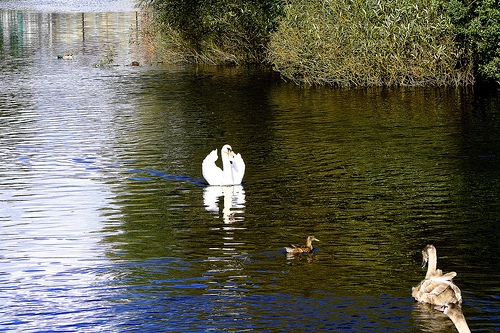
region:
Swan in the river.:
[199, 139, 246, 189]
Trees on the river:
[132, 1, 498, 99]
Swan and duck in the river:
[190, 130, 331, 270]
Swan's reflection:
[200, 181, 250, 229]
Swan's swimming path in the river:
[72, 146, 205, 189]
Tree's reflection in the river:
[275, 80, 462, 286]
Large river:
[0, 6, 488, 328]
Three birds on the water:
[200, 141, 465, 311]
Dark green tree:
[138, 0, 273, 67]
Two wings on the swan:
[200, 145, 247, 187]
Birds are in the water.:
[203, 145, 469, 330]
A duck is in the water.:
[279, 228, 319, 259]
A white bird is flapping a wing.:
[198, 144, 248, 187]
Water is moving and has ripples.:
[3, 0, 493, 327]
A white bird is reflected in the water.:
[200, 145, 247, 230]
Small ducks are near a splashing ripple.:
[58, 50, 140, 67]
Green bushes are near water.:
[136, 0, 496, 91]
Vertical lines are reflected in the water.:
[2, 0, 140, 45]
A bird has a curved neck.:
[414, 242, 476, 331]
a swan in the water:
[200, 138, 252, 191]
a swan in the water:
[409, 242, 474, 330]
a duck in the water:
[278, 233, 328, 262]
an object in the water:
[48, 50, 78, 64]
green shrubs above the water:
[127, 0, 496, 89]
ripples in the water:
[18, 132, 198, 201]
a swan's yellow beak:
[227, 148, 234, 156]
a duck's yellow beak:
[313, 235, 319, 245]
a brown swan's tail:
[440, 293, 479, 332]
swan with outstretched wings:
[189, 126, 295, 210]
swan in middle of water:
[191, 124, 268, 204]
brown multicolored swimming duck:
[283, 225, 365, 290]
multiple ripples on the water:
[348, 139, 398, 224]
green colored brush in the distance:
[283, 18, 368, 75]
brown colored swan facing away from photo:
[401, 233, 479, 330]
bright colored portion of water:
[28, 107, 61, 202]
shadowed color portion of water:
[332, 118, 421, 209]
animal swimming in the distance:
[37, 42, 86, 68]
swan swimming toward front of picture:
[183, 130, 276, 214]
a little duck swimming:
[282, 230, 321, 254]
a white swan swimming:
[199, 141, 247, 188]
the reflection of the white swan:
[206, 185, 250, 229]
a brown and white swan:
[411, 240, 476, 332]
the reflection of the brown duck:
[283, 250, 322, 265]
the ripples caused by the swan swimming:
[74, 151, 197, 191]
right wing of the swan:
[199, 148, 221, 186]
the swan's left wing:
[236, 148, 252, 185]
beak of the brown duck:
[312, 237, 318, 242]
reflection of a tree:
[74, 11, 90, 51]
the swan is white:
[183, 129, 274, 199]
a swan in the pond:
[193, 142, 267, 196]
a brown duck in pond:
[389, 228, 480, 332]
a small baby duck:
[272, 225, 323, 266]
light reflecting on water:
[18, 90, 138, 302]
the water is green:
[314, 87, 479, 177]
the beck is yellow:
[225, 148, 237, 155]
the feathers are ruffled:
[196, 133, 248, 188]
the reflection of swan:
[201, 182, 254, 223]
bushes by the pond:
[126, 5, 463, 88]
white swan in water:
[193, 137, 258, 201]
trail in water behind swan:
[75, 131, 252, 197]